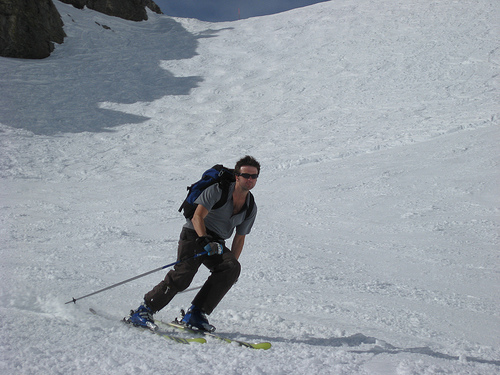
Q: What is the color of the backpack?
A: Blue with black straps.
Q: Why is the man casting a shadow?
A: The angle of the sun allows it.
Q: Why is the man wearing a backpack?
A: It contains his belongings.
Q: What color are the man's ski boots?
A: Black and blue.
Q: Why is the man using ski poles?
A: To guide him.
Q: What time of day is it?
A: Afternoon.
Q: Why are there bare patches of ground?
A: Melted by sunlight.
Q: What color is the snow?
A: White.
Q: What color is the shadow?
A: Gray.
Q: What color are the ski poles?
A: Gray.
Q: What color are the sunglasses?
A: Black.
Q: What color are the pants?
A: Black.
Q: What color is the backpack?
A: Blue.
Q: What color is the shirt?
A: Gray.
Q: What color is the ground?
A: White.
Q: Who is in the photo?
A: A skier.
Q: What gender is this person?
A: Male.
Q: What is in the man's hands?
A: Ski poles.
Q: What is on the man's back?
A: A backpack.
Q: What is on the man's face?
A: Sunglasses.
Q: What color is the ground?
A: White.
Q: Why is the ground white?
A: Snow.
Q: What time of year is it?
A: Winter.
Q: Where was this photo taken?
A: At a ski resort.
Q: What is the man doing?
A: Skiing.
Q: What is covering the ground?
A: Snow.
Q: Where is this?
A: Ski slope.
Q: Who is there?
A: Skier.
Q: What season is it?
A: Winter.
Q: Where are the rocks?
A: Left.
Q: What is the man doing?
A: Skiing.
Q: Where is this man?
A: On a mountain.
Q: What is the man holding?
A: Ski poles.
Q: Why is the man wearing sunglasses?
A: It's sunny.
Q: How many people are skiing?
A: One.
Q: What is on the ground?
A: Snow.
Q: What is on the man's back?
A: Backpack.